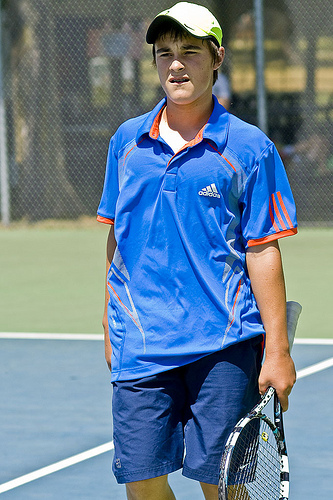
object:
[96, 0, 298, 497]
boy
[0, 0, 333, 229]
fence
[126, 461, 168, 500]
knee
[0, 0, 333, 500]
court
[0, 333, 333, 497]
pavement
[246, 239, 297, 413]
part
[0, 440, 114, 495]
line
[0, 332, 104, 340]
line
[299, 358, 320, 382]
line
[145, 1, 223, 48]
hat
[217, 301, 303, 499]
racket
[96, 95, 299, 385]
shirt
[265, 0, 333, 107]
trees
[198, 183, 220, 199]
logo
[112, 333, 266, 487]
shorts